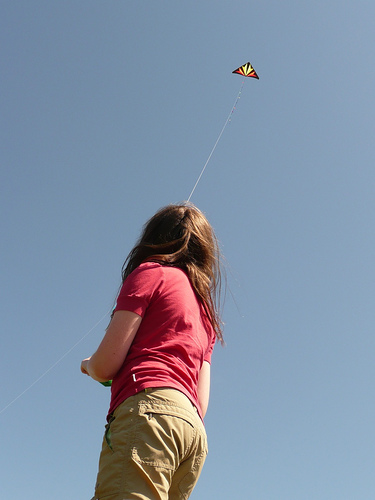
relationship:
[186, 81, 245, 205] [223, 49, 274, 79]
string attached to kite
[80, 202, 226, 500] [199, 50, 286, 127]
girl flying a kite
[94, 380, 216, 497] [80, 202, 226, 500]
brown pants on a girl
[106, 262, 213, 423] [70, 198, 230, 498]
red shirt on a woman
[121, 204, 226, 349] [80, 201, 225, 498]
hair on a woman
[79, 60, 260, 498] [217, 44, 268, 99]
girl kite flyng a kite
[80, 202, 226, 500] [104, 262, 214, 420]
girl wearing a red shirt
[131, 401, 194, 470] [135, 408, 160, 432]
pocket closes with a zipper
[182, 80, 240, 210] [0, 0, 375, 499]
string in blue sky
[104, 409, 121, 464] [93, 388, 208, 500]
pocket on brown pants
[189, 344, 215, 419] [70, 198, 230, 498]
arm of woman